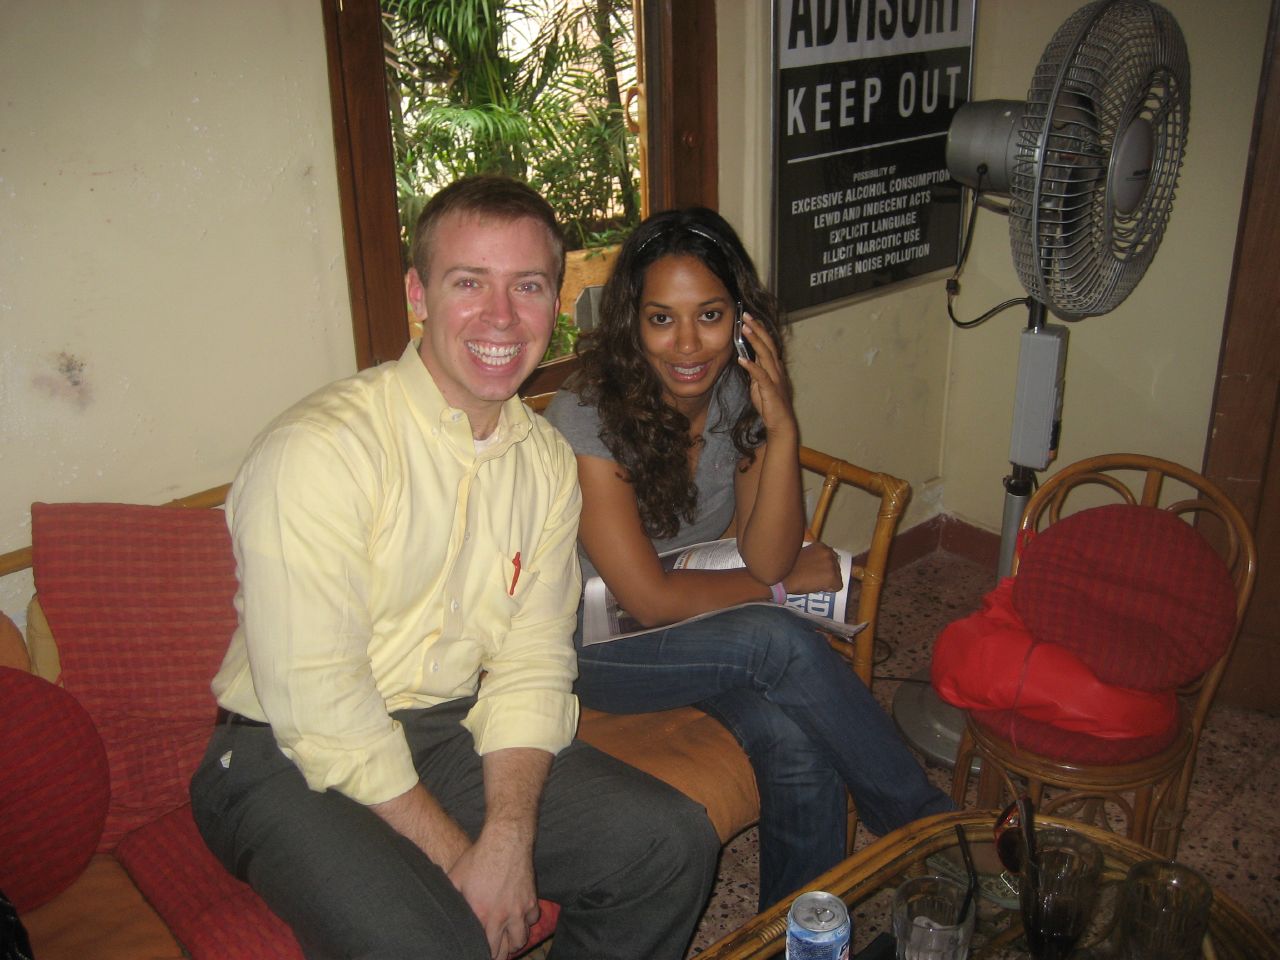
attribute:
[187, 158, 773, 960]
male — caucasian, smiling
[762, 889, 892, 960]
drink — canned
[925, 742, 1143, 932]
tumblers — glass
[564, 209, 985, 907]
lady — african american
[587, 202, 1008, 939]
female — holding